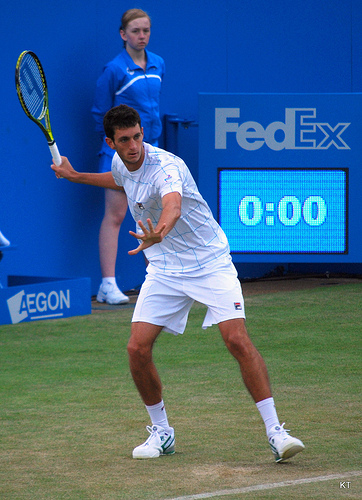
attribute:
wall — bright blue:
[210, 32, 349, 100]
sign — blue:
[189, 82, 359, 267]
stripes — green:
[154, 434, 178, 455]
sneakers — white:
[130, 421, 177, 461]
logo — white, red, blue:
[234, 299, 244, 313]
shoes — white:
[133, 424, 306, 465]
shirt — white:
[110, 139, 231, 273]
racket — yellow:
[11, 47, 61, 165]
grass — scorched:
[255, 275, 357, 420]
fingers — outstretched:
[128, 219, 168, 255]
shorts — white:
[128, 257, 247, 335]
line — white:
[169, 449, 361, 498]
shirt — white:
[96, 146, 226, 273]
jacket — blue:
[95, 48, 168, 133]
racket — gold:
[4, 38, 58, 167]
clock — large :
[234, 162, 322, 245]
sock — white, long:
[253, 389, 285, 419]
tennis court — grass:
[2, 5, 351, 488]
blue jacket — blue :
[101, 51, 160, 141]